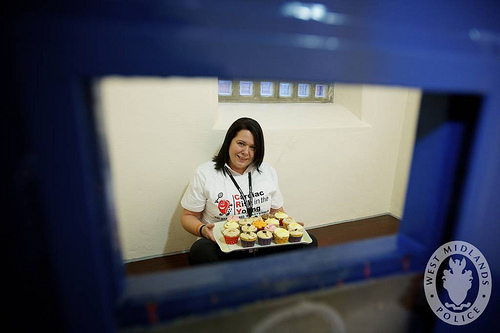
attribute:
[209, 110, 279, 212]
woman — sitting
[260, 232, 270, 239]
cupcake — purple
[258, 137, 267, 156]
hair — black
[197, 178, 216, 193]
t-shirt — white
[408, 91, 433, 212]
window — blue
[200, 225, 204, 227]
band — orange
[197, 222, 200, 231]
band — black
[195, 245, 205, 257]
pants — black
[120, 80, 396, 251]
room — cell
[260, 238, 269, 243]
liner — purple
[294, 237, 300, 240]
liner — purple